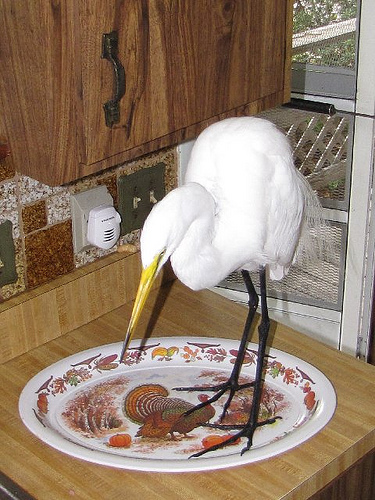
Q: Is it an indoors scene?
A: Yes, it is indoors.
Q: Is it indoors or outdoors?
A: It is indoors.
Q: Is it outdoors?
A: No, it is indoors.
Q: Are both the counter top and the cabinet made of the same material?
A: Yes, both the counter top and the cabinet are made of wood.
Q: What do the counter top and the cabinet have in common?
A: The material, both the counter top and the cabinet are wooden.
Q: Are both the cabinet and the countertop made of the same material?
A: Yes, both the cabinet and the countertop are made of wood.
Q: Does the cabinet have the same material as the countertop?
A: Yes, both the cabinet and the countertop are made of wood.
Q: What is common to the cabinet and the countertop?
A: The material, both the cabinet and the countertop are wooden.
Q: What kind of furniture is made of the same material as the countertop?
A: The cabinet is made of the same material as the countertop.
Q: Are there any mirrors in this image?
A: No, there are no mirrors.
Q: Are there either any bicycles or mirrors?
A: No, there are no mirrors or bicycles.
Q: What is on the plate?
A: The turkey is on the plate.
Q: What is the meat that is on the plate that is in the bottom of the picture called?
A: The meat is turkey.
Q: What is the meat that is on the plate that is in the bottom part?
A: The meat is turkey.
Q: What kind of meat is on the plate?
A: The meat is turkey.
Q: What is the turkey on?
A: The turkey is on the plate.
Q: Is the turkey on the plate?
A: Yes, the turkey is on the plate.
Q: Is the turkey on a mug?
A: No, the turkey is on the plate.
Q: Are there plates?
A: Yes, there is a plate.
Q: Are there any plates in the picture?
A: Yes, there is a plate.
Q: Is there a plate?
A: Yes, there is a plate.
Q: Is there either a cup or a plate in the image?
A: Yes, there is a plate.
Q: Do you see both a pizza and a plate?
A: No, there is a plate but no pizzas.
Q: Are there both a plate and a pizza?
A: No, there is a plate but no pizzas.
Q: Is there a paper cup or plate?
A: Yes, there is a paper plate.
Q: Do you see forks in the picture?
A: No, there are no forks.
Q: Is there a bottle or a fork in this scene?
A: No, there are no forks or bottles.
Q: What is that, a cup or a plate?
A: That is a plate.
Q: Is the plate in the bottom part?
A: Yes, the plate is in the bottom of the image.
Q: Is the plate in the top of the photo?
A: No, the plate is in the bottom of the image.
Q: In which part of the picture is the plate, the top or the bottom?
A: The plate is in the bottom of the image.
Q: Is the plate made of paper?
A: Yes, the plate is made of paper.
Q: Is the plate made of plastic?
A: No, the plate is made of paper.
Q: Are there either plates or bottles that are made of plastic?
A: No, there is a plate but it is made of paper.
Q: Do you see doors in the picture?
A: Yes, there is a door.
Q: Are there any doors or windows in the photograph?
A: Yes, there is a door.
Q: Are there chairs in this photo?
A: No, there are no chairs.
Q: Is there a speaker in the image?
A: No, there are no speakers.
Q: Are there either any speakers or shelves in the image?
A: No, there are no speakers or shelves.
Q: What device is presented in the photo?
A: The device is a screen.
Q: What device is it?
A: The device is a screen.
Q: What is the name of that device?
A: This is a screen.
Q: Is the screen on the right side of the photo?
A: Yes, the screen is on the right of the image.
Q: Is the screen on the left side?
A: No, the screen is on the right of the image.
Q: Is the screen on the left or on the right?
A: The screen is on the right of the image.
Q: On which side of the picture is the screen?
A: The screen is on the right of the image.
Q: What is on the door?
A: The screen is on the door.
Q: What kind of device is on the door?
A: The device is a screen.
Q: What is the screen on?
A: The screen is on the door.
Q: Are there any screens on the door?
A: Yes, there is a screen on the door.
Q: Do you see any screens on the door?
A: Yes, there is a screen on the door.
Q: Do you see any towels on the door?
A: No, there is a screen on the door.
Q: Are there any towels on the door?
A: No, there is a screen on the door.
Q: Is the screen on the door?
A: Yes, the screen is on the door.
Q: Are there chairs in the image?
A: No, there are no chairs.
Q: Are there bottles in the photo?
A: No, there are no bottles.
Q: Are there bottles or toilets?
A: No, there are no bottles or toilets.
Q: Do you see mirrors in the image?
A: No, there are no mirrors.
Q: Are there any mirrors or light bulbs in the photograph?
A: No, there are no mirrors or light bulbs.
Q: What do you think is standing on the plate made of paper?
A: The crane is standing on the plate.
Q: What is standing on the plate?
A: The crane is standing on the plate.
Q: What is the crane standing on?
A: The crane is standing on the plate.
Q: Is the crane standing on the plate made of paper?
A: Yes, the crane is standing on the plate.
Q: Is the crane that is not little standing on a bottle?
A: No, the crane is standing on the plate.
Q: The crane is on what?
A: The crane is on the countertop.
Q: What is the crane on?
A: The crane is on the countertop.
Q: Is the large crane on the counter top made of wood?
A: Yes, the crane is on the counter top.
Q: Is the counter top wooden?
A: Yes, the counter top is wooden.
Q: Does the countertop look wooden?
A: Yes, the countertop is wooden.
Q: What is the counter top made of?
A: The counter top is made of wood.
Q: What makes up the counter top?
A: The counter top is made of wood.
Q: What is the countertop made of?
A: The counter top is made of wood.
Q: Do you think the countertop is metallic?
A: No, the countertop is wooden.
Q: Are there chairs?
A: No, there are no chairs.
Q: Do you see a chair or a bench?
A: No, there are no chairs or benches.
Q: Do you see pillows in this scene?
A: No, there are no pillows.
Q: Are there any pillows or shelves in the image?
A: No, there are no pillows or shelves.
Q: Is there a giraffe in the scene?
A: No, there are no giraffes.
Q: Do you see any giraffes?
A: No, there are no giraffes.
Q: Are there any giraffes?
A: No, there are no giraffes.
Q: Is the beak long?
A: Yes, the beak is long.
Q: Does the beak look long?
A: Yes, the beak is long.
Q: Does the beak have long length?
A: Yes, the beak is long.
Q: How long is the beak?
A: The beak is long.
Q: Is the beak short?
A: No, the beak is long.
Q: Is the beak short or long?
A: The beak is long.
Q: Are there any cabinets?
A: Yes, there is a cabinet.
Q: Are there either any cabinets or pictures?
A: Yes, there is a cabinet.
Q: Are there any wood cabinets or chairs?
A: Yes, there is a wood cabinet.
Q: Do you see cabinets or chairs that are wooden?
A: Yes, the cabinet is wooden.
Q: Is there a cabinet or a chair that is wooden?
A: Yes, the cabinet is wooden.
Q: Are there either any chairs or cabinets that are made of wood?
A: Yes, the cabinet is made of wood.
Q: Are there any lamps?
A: No, there are no lamps.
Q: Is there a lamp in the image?
A: No, there are no lamps.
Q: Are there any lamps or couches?
A: No, there are no lamps or couches.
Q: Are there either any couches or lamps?
A: No, there are no lamps or couches.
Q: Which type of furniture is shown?
A: The furniture is a cabinet.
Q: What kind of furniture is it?
A: The piece of furniture is a cabinet.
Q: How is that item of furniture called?
A: This is a cabinet.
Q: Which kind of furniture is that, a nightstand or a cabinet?
A: This is a cabinet.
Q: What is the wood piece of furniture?
A: The piece of furniture is a cabinet.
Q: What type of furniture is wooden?
A: The furniture is a cabinet.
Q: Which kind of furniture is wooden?
A: The furniture is a cabinet.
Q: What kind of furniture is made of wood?
A: The furniture is a cabinet.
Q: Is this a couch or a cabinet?
A: This is a cabinet.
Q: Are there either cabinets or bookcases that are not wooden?
A: No, there is a cabinet but it is wooden.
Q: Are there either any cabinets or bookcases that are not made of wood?
A: No, there is a cabinet but it is made of wood.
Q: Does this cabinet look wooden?
A: Yes, the cabinet is wooden.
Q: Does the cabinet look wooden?
A: Yes, the cabinet is wooden.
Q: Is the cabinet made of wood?
A: Yes, the cabinet is made of wood.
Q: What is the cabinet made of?
A: The cabinet is made of wood.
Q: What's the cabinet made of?
A: The cabinet is made of wood.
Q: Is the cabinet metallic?
A: No, the cabinet is wooden.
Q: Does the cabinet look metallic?
A: No, the cabinet is wooden.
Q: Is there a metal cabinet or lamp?
A: No, there is a cabinet but it is wooden.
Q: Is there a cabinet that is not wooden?
A: No, there is a cabinet but it is wooden.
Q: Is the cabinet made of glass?
A: No, the cabinet is made of wood.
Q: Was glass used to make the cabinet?
A: No, the cabinet is made of wood.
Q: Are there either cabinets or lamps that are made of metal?
A: No, there is a cabinet but it is made of wood.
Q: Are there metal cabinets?
A: No, there is a cabinet but it is made of wood.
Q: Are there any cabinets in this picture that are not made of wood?
A: No, there is a cabinet but it is made of wood.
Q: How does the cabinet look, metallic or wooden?
A: The cabinet is wooden.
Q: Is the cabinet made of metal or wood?
A: The cabinet is made of wood.